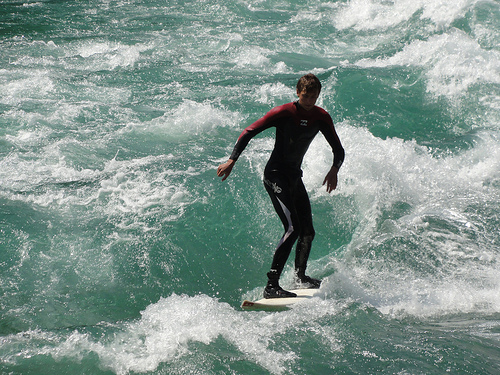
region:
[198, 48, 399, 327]
surfer on a surfboard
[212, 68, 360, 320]
man on a surfboard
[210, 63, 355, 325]
person on a surfboard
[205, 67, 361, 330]
young man on a surfboard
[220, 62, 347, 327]
man in a wetsuit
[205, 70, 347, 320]
surfer in a wetsuit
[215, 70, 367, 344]
person in a wetsuit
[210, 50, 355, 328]
man facing to the right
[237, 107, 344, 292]
red, black and gray wetsuit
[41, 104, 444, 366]
tumultuous water surface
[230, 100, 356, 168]
a surfers red wetsuit top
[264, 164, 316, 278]
a surfers black and white wet suit pants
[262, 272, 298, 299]
the surfers black surfing boot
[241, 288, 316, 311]
a white surfboard with a red tip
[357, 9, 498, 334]
a choppy body of water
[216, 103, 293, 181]
the surfers arm is extended for balance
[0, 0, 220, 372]
choopy water making white water splash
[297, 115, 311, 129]
the logo or brand of the wetsuit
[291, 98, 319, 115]
a black trim around the neck of the wetsuit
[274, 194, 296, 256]
a white stripe on the side of the pant leg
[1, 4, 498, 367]
The water is choppy.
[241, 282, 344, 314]
The surfboard is wet.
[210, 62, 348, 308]
The boy is on a surfboard.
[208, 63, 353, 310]
The boy is wearing a wetsuit.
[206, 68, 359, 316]
The wetsuit is wet.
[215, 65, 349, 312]
The boy has hair.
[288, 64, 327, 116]
The boy's hair is short.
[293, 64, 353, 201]
The boy's arm is slightly bent.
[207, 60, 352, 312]
The boy's knees are slightly bent.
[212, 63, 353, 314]
The boy is standing on the surfboard.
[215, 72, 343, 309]
A person on a surf board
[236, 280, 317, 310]
A white surf board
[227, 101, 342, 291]
A red and black wet suit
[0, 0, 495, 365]
A large body of water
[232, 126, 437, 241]
A wave crashing down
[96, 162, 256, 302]
A wave about to crest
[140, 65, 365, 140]
A small wave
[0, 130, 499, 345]
A large wave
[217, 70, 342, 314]
A man riding a wave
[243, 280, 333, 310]
A surfboard on the water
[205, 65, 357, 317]
a surfer in the ocean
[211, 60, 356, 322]
surfer wears a wetsuit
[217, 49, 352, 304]
wet suit of surfer is black and red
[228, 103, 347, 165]
top of wetsuit is red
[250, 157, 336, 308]
pants of wetsuit is black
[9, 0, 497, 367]
water of ocean is choppy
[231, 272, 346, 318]
surfboard is white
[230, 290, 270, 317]
nose of surfboard is pointy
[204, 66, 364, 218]
hands of surfer are on side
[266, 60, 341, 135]
surfer has short hair